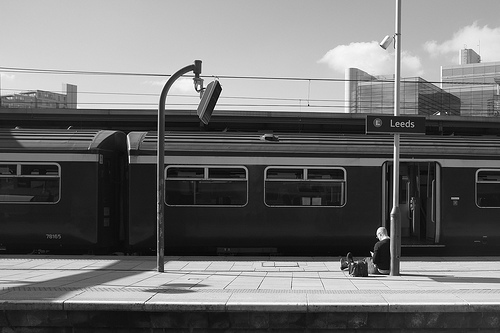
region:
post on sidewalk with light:
[378, 3, 415, 283]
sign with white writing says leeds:
[365, 101, 429, 143]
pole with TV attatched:
[142, 53, 228, 285]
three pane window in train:
[144, 153, 259, 217]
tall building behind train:
[337, 59, 467, 122]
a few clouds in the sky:
[313, 36, 496, 89]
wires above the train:
[18, 55, 497, 117]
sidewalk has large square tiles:
[138, 253, 494, 320]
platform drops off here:
[101, 281, 488, 331]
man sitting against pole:
[337, 204, 420, 274]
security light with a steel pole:
[145, 47, 242, 284]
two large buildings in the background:
[332, 40, 499, 115]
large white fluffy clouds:
[309, 15, 493, 102]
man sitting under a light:
[320, 214, 417, 284]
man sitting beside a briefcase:
[325, 213, 407, 300]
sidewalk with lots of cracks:
[45, 262, 425, 312]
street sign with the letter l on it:
[323, 103, 448, 159]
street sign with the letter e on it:
[315, 111, 450, 148]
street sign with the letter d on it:
[328, 107, 448, 169]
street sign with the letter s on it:
[320, 98, 451, 172]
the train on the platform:
[127, 122, 479, 259]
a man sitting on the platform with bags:
[342, 216, 409, 296]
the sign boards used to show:
[355, 106, 447, 149]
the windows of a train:
[257, 154, 353, 218]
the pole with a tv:
[145, 44, 230, 284]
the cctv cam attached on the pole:
[367, 21, 414, 67]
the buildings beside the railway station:
[429, 40, 496, 105]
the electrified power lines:
[250, 51, 355, 121]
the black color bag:
[341, 254, 378, 296]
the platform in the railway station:
[184, 269, 249, 331]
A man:
[335, 211, 401, 281]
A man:
[346, 173, 408, 311]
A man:
[349, 191, 380, 298]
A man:
[371, 196, 423, 307]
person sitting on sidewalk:
[325, 223, 391, 278]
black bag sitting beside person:
[303, 218, 393, 301]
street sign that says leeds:
[305, 106, 427, 166]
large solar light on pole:
[133, 79, 227, 296]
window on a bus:
[0, 158, 68, 244]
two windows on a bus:
[149, 155, 350, 254]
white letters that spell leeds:
[375, 110, 422, 140]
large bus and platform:
[47, 89, 408, 266]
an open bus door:
[342, 150, 441, 257]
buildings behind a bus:
[337, 79, 490, 179]